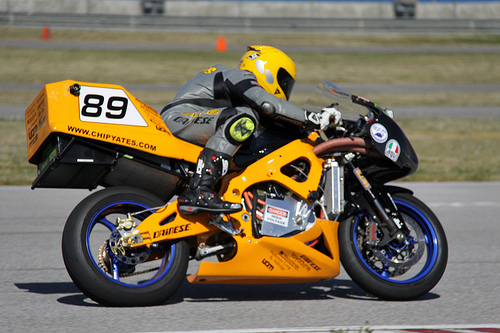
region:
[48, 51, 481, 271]
this is a motorbike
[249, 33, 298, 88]
this is a helmet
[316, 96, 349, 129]
this is a glove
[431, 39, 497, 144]
this is a grass area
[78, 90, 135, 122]
this is a writing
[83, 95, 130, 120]
the writing is in black in color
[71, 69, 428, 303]
the motorbike is on a highway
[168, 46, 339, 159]
the man is riding the motorbike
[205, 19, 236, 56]
the cone is at the background road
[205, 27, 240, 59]
the cone is pink in color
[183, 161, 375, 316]
the notorbike is orange in color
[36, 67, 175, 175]
the seat is orange in color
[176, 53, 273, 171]
the outfit is gray in color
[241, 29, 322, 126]
the helmet is light orange in color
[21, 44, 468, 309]
person on motorized bike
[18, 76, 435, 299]
bike on the road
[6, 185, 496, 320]
surface bike rides on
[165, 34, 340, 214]
rider on the bike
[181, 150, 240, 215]
boot on the person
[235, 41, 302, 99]
helmet on the rider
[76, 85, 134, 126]
number on the bike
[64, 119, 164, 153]
site info on the bike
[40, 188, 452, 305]
tires on the bike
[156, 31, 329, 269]
this is a motorbike racer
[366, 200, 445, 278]
this is the wheel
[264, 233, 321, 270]
the motorbike is yellow in color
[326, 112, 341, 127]
this is the steering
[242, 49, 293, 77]
this is an helmet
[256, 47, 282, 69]
the helmet is yellow in color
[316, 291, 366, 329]
this is the path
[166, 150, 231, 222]
this is the leg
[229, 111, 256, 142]
this is the knee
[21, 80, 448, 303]
A dark yellow racing motorcycle being driven by a man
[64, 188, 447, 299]
High performance motorcycle tires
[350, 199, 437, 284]
Stylish, dark blue motorcycle wheel rims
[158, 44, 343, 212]
A motorcycle racer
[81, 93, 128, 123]
The motor cycle's racing number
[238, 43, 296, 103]
A sturdy, yellow helmet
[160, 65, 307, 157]
A gray, skin-tight, motorcycle race suit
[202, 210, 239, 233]
The motorcycle's pedal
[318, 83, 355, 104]
The glass windshield of the motorcycle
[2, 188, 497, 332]
The gray, concrete racing track